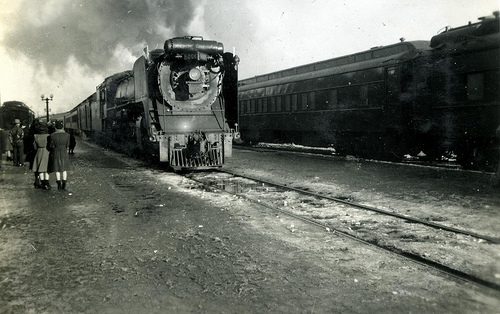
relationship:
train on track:
[62, 36, 240, 173] [210, 177, 477, 290]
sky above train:
[0, 1, 497, 116] [52, 28, 245, 178]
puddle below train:
[179, 170, 499, 265] [79, 39, 234, 172]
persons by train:
[20, 119, 34, 160] [79, 39, 234, 172]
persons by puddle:
[32, 117, 49, 184] [179, 170, 499, 265]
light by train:
[179, 67, 208, 90] [32, 36, 238, 171]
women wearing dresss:
[28, 122, 75, 189] [51, 132, 68, 171]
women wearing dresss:
[28, 122, 75, 189] [36, 132, 45, 172]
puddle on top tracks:
[191, 171, 274, 196] [181, 167, 498, 292]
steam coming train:
[5, 1, 200, 41] [52, 28, 245, 178]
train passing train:
[32, 36, 238, 171] [237, 12, 498, 162]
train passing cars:
[32, 36, 238, 171] [249, 47, 426, 154]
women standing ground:
[30, 119, 74, 194] [18, 188, 176, 264]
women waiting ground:
[30, 119, 74, 194] [18, 188, 176, 264]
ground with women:
[18, 188, 176, 264] [30, 119, 74, 194]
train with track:
[52, 28, 245, 178] [194, 166, 499, 298]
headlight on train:
[156, 130, 238, 165] [95, 43, 259, 173]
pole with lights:
[37, 91, 56, 131] [34, 95, 55, 102]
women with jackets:
[22, 113, 99, 195] [50, 137, 69, 168]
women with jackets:
[22, 113, 99, 195] [33, 133, 48, 169]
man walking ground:
[12, 117, 22, 169] [430, 135, 455, 178]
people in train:
[33, 122, 68, 187] [64, 41, 244, 168]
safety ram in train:
[168, 145, 224, 172] [52, 28, 245, 178]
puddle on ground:
[179, 170, 499, 265] [184, 160, 496, 291]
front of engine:
[152, 32, 232, 172] [96, 32, 241, 169]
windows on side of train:
[240, 79, 387, 116] [236, 15, 499, 175]